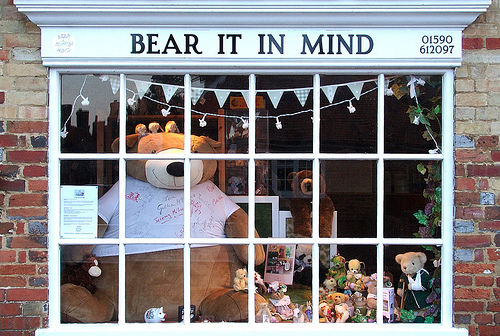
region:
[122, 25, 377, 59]
name on the building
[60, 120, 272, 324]
bear behind the window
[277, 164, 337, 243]
bear behind the window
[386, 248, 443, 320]
bear behind the window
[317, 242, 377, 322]
lots of bears behind the window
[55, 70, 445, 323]
window in the building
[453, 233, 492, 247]
brick in the building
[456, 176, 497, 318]
bricks in the building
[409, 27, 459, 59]
numbers on the building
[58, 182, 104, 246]
sign in the window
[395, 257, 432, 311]
Teddy bear with a cast arm.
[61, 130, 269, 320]
Big teddy bear in a store.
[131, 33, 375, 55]
Bear it in Mind is a store of teddy bears.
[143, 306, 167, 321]
Little black pig in a store.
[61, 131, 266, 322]
Big teddy bear with a white t-shirt.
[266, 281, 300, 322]
Little teddy bear with a dress.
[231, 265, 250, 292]
Little teddy bear in the lap of a big bear.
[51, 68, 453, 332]
Window at the store in which there are a lot of bears.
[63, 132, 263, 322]
Teddy bear with a smile face.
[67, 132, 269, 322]
Big bear color brown.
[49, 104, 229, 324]
Large teddy bear in window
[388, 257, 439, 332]
Small teddy bear with cast and sling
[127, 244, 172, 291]
Reflection in the window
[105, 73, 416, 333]
Window has lots of panes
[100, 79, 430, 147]
Lights hanging down on top of window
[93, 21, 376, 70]
Sign for the store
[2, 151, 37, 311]
Bricks beside the window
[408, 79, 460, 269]
Vine on the window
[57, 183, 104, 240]
Sign on the window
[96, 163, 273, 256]
Teddy bear is wearing a shirt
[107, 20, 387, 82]
black letters on sign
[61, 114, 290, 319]
bear seen through window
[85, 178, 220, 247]
bear's shirt is white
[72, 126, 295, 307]
the bear is brown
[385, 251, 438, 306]
bear's shirt is green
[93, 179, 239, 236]
writing on bear's shirt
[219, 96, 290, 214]
brown shelf in distance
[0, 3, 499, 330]
building made of brick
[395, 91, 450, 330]
leaves in corner of window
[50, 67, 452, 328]
window frame is white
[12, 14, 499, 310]
a business store window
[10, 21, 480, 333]
a window with a display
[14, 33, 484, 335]
bears on display in a window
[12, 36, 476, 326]
a large bear in a window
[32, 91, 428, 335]
a large bear on display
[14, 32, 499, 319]
a large window on a brick building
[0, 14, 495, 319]
brick building with a window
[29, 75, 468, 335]
bears for sale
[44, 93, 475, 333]
teddy bears in a window